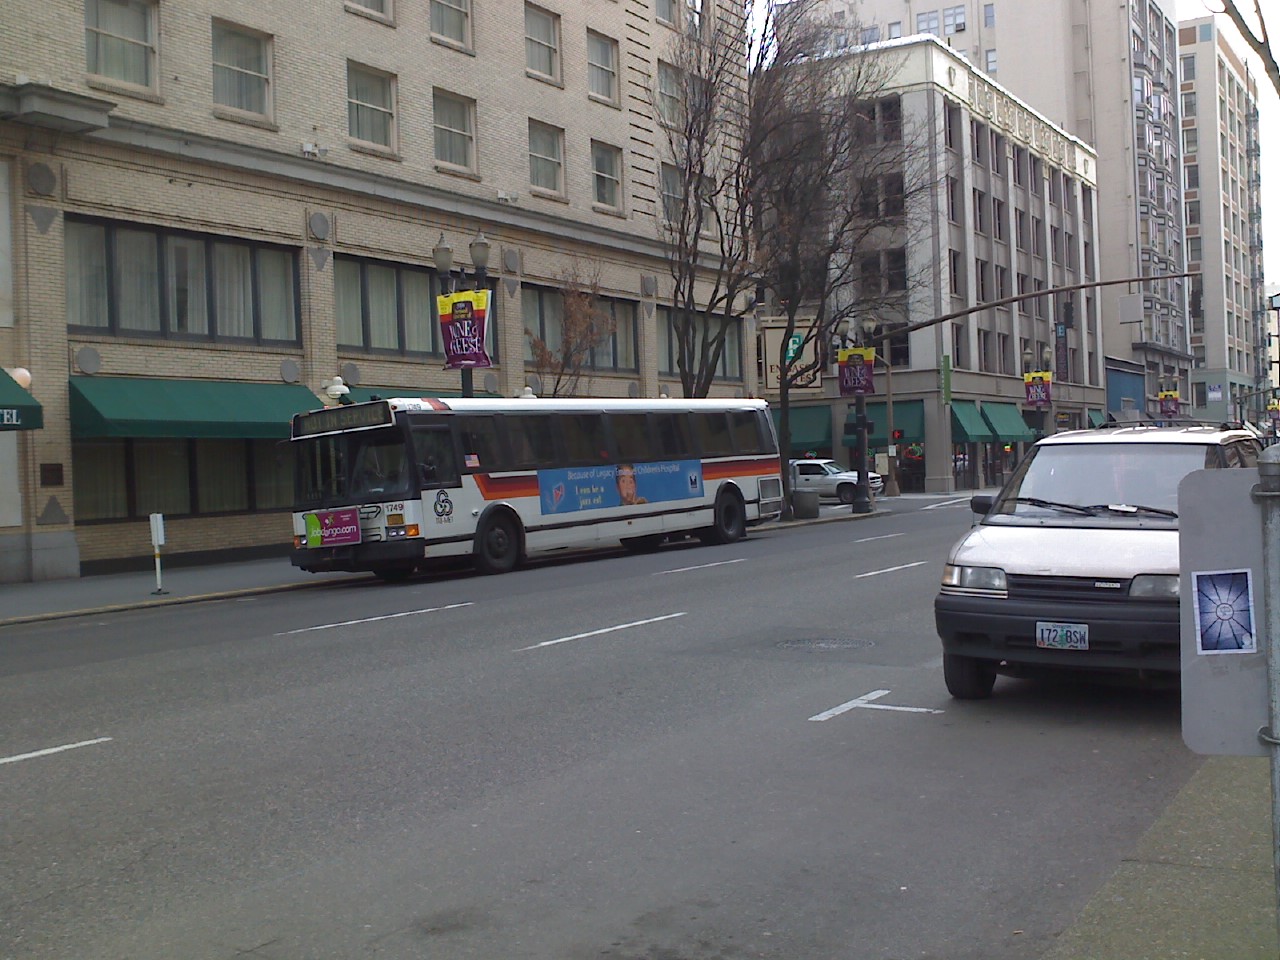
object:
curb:
[30, 558, 345, 613]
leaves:
[656, 19, 879, 351]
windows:
[65, 201, 311, 361]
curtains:
[61, 213, 305, 353]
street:
[30, 479, 1241, 925]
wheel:
[479, 504, 532, 578]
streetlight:
[433, 281, 492, 395]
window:
[205, 10, 280, 121]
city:
[8, 4, 1278, 940]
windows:
[392, 405, 800, 483]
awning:
[979, 391, 1036, 449]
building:
[746, 28, 1118, 495]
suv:
[929, 412, 1278, 709]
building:
[18, 10, 780, 568]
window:
[325, 223, 372, 341]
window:
[605, 284, 662, 395]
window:
[863, 75, 920, 141]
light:
[835, 258, 1121, 472]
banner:
[1018, 343, 1073, 438]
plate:
[1026, 611, 1107, 655]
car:
[949, 402, 1233, 703]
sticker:
[1193, 566, 1260, 663]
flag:
[431, 439, 492, 508]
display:
[272, 394, 410, 449]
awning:
[39, 360, 327, 491]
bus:
[286, 377, 808, 579]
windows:
[579, 139, 622, 214]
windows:
[536, 117, 568, 189]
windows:
[425, 78, 500, 175]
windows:
[345, 65, 398, 143]